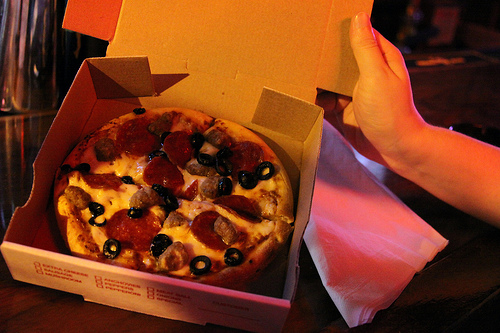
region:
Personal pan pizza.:
[47, 90, 289, 287]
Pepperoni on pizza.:
[105, 203, 166, 249]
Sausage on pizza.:
[155, 240, 189, 269]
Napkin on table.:
[300, 117, 443, 331]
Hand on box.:
[321, 27, 423, 145]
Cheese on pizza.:
[96, 190, 129, 204]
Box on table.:
[3, 252, 288, 331]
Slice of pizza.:
[172, 119, 293, 224]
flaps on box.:
[55, 45, 320, 122]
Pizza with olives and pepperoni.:
[48, 103, 292, 282]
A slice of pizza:
[141, 196, 297, 285]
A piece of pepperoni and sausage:
[192, 209, 236, 251]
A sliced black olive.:
[101, 236, 119, 260]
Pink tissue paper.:
[303, 113, 448, 328]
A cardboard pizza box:
[3, 0, 377, 330]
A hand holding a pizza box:
[318, 11, 424, 167]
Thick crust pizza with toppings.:
[51, 104, 293, 286]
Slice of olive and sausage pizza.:
[179, 109, 302, 222]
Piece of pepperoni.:
[112, 117, 157, 157]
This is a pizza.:
[61, 97, 310, 291]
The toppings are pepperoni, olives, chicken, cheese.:
[58, 99, 293, 330]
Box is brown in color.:
[164, 14, 269, 77]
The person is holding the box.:
[303, 11, 448, 213]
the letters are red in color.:
[21, 251, 242, 327]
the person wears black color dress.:
[383, 258, 464, 331]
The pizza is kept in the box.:
[63, 50, 310, 267]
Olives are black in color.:
[150, 235, 172, 253]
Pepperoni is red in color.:
[109, 206, 164, 241]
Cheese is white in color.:
[71, 121, 274, 270]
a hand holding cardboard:
[333, 10, 414, 134]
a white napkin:
[346, 183, 419, 320]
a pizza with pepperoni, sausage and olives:
[58, 97, 293, 284]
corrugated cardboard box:
[76, 40, 308, 116]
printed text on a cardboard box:
[17, 257, 140, 302]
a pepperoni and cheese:
[141, 155, 188, 189]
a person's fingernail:
[353, 9, 373, 27]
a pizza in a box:
[12, 80, 317, 293]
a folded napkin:
[291, 232, 464, 312]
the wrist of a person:
[366, 103, 452, 183]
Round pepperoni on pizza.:
[101, 203, 160, 250]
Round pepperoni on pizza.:
[188, 208, 238, 253]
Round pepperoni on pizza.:
[136, 151, 186, 192]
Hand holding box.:
[336, 6, 423, 162]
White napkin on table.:
[301, 111, 450, 328]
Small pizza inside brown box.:
[45, 105, 296, 292]